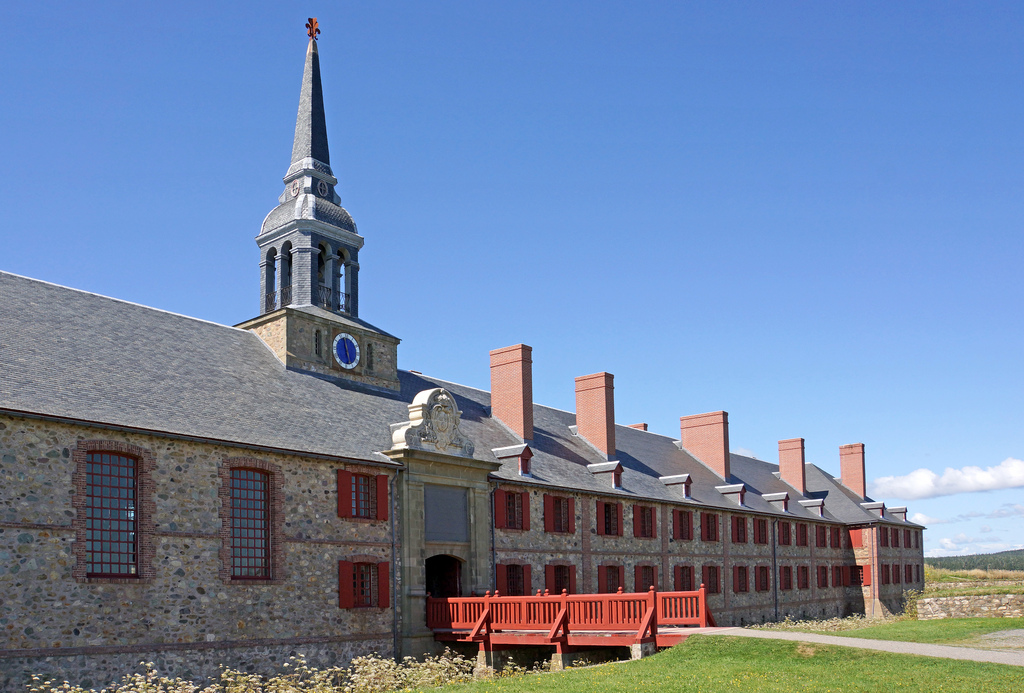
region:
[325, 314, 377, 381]
blue and white clock in tower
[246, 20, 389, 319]
gray steeple of building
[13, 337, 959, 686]
large tan and red building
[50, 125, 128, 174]
white clouds in blue sky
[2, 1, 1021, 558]
blue sky with few clouds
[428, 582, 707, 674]
wooden bridge over trench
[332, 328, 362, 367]
clock with blue face below spire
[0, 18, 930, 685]
long brick building with tall spire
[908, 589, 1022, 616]
low brick wall at end of building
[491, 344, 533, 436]
first brick chimney in row of five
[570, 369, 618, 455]
second brick chimney in row of five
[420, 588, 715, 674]
short and red bridge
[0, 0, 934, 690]
building has a pointed tower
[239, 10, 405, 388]
tower has a red decoration on top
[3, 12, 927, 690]
building has many brown stacks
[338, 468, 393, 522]
window frame is red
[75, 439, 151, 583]
window has safety bars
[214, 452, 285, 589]
window has a stone frame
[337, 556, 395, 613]
window has a red frame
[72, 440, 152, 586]
window has a stone frame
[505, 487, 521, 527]
window in front of church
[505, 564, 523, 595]
window in front of church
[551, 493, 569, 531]
window in front of church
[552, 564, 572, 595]
window in front of church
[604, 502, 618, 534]
window in front of church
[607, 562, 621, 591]
window in front of church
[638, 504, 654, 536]
window in front of church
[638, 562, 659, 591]
window in front of church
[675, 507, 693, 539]
window in front of church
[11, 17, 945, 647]
large tan and red building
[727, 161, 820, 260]
white clouds in blue sky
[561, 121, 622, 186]
white clouds in blue sky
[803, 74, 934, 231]
white clouds in blue sky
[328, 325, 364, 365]
clock on the tower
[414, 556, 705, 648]
red bridge on the building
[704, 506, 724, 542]
window with shutters on the building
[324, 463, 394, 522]
window with shutters on the building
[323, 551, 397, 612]
window with shutters on the building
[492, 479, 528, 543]
window with shutters on the building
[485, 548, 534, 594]
window with shutters on the building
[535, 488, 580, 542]
window with shutters on the building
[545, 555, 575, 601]
window with shutters on the building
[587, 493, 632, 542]
window with shutters on the building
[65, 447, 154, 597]
A window on a building.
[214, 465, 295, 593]
A window on a building.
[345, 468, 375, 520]
A window on a building.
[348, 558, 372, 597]
A window on a building.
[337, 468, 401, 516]
A window on a building.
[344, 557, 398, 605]
A window on a building.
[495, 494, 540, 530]
A window on a building.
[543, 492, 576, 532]
A window on a building.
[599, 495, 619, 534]
A window on a building.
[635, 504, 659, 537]
A window on a building.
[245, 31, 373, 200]
a steeple that is tall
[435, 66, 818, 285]
a sky that is blue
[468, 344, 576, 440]
a chimney that is red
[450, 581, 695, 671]
a bridge that is red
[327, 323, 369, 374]
Blue and white clock on tower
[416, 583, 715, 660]
Red bridge across walkway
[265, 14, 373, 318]
Steeple to the church